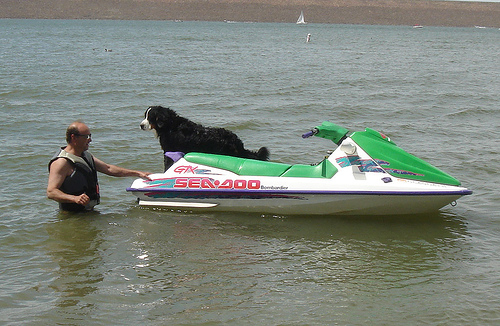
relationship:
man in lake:
[45, 120, 153, 216] [1, 19, 499, 325]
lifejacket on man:
[47, 143, 102, 209] [45, 120, 153, 216]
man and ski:
[45, 120, 153, 216] [125, 119, 474, 219]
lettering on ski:
[174, 176, 262, 190] [125, 119, 474, 219]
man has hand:
[45, 120, 153, 216] [138, 168, 153, 184]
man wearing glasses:
[45, 120, 153, 216] [75, 134, 93, 140]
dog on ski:
[139, 104, 270, 168] [125, 119, 474, 219]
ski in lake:
[125, 119, 474, 219] [1, 19, 499, 325]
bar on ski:
[302, 119, 353, 150] [125, 119, 474, 219]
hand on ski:
[138, 168, 153, 184] [125, 119, 474, 219]